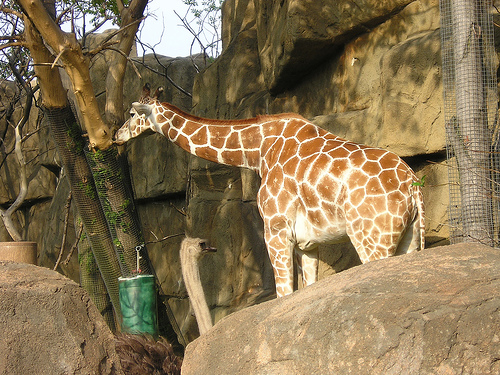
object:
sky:
[3, 1, 227, 72]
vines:
[75, 142, 134, 261]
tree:
[2, 2, 182, 359]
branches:
[2, 14, 210, 104]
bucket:
[118, 271, 158, 333]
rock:
[179, 229, 499, 373]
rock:
[2, 256, 118, 373]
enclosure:
[3, 0, 499, 372]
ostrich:
[176, 230, 216, 336]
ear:
[129, 98, 156, 119]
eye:
[126, 111, 136, 121]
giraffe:
[111, 81, 432, 301]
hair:
[152, 97, 299, 127]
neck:
[154, 106, 297, 176]